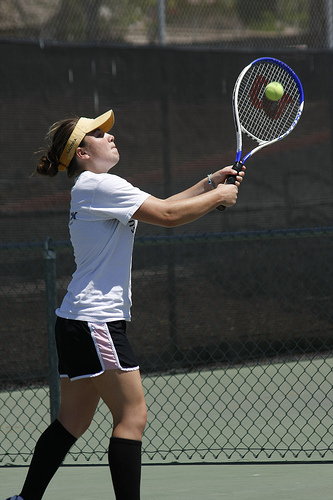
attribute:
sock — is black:
[104, 435, 153, 499]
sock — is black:
[21, 416, 81, 498]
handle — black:
[215, 161, 244, 210]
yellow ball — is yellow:
[262, 80, 287, 104]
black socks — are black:
[107, 437, 142, 498]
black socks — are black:
[19, 417, 77, 498]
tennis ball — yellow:
[264, 82, 292, 99]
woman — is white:
[20, 114, 158, 493]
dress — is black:
[57, 167, 145, 377]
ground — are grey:
[0, 359, 330, 498]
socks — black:
[106, 433, 145, 498]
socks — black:
[17, 418, 76, 498]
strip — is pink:
[85, 321, 123, 374]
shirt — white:
[54, 169, 152, 321]